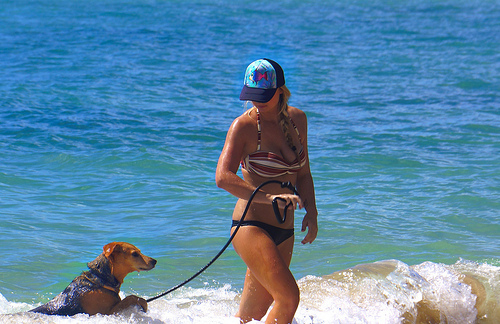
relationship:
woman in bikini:
[208, 51, 328, 322] [227, 100, 303, 241]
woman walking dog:
[208, 51, 328, 322] [32, 226, 170, 315]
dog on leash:
[32, 231, 159, 322] [132, 177, 306, 309]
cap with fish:
[237, 57, 285, 102] [244, 66, 274, 86]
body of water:
[4, 4, 494, 323] [2, 1, 498, 322]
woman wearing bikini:
[208, 51, 328, 322] [223, 99, 299, 251]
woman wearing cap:
[208, 51, 328, 322] [235, 57, 289, 114]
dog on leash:
[32, 231, 159, 322] [143, 174, 304, 302]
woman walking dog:
[208, 51, 328, 322] [32, 231, 159, 322]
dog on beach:
[32, 231, 159, 322] [1, 272, 498, 322]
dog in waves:
[32, 231, 159, 322] [1, 256, 498, 320]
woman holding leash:
[208, 51, 328, 322] [143, 174, 304, 302]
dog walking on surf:
[32, 231, 159, 322] [2, 248, 498, 323]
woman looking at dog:
[208, 51, 328, 322] [32, 231, 159, 322]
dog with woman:
[32, 231, 159, 322] [208, 51, 328, 322]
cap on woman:
[237, 57, 285, 102] [208, 51, 328, 322]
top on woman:
[236, 106, 309, 182] [208, 51, 328, 322]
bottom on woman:
[225, 214, 303, 254] [208, 51, 328, 322]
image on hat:
[247, 64, 268, 85] [230, 53, 290, 105]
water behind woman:
[2, 1, 498, 322] [208, 51, 328, 322]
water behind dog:
[2, 1, 498, 322] [32, 231, 159, 322]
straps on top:
[246, 105, 309, 156] [239, 94, 315, 181]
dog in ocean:
[32, 231, 159, 322] [5, 4, 498, 321]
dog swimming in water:
[32, 231, 159, 322] [2, 1, 498, 322]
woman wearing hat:
[208, 51, 328, 322] [230, 53, 290, 105]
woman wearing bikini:
[208, 51, 328, 322] [227, 100, 303, 241]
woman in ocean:
[208, 51, 328, 322] [5, 4, 498, 321]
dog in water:
[32, 231, 159, 322] [2, 1, 498, 322]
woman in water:
[208, 51, 328, 322] [2, 1, 498, 322]